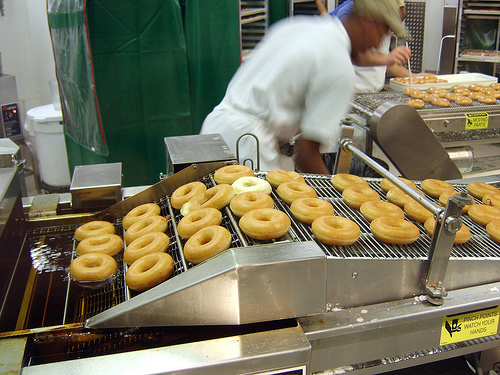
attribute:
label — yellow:
[437, 313, 483, 347]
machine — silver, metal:
[5, 127, 484, 373]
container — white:
[16, 101, 79, 190]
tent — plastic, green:
[44, 2, 247, 190]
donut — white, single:
[230, 169, 273, 199]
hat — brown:
[346, 0, 416, 45]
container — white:
[389, 67, 483, 97]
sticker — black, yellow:
[429, 312, 483, 351]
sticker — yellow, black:
[460, 110, 483, 132]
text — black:
[457, 312, 483, 332]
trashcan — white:
[16, 100, 71, 190]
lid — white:
[20, 100, 64, 124]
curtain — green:
[41, 1, 243, 191]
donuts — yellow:
[141, 185, 401, 251]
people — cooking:
[195, 0, 447, 181]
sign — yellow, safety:
[427, 308, 497, 354]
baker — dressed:
[211, 13, 360, 150]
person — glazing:
[339, 10, 443, 120]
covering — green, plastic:
[94, 13, 224, 158]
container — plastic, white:
[26, 84, 102, 206]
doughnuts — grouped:
[162, 160, 412, 264]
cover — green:
[57, 10, 237, 152]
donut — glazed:
[318, 207, 366, 247]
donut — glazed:
[59, 242, 146, 294]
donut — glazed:
[76, 227, 151, 267]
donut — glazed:
[65, 219, 116, 248]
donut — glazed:
[130, 249, 192, 284]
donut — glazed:
[105, 219, 181, 265]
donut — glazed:
[108, 208, 173, 245]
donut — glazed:
[241, 207, 306, 242]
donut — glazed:
[206, 180, 279, 210]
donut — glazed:
[294, 196, 331, 226]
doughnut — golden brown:
[72, 254, 115, 284]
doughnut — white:
[229, 175, 269, 193]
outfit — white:
[202, 15, 346, 174]